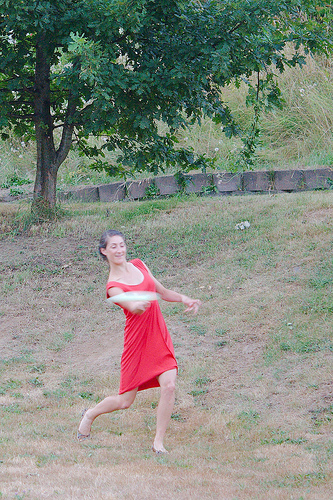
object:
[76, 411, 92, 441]
shoe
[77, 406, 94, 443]
foot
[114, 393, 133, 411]
knees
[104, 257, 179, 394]
dress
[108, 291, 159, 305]
frisbee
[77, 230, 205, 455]
woman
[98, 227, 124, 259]
hair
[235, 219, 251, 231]
leaf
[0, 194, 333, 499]
ground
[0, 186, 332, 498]
grass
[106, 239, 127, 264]
face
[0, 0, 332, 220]
tree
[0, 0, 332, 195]
grass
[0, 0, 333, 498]
park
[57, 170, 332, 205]
wall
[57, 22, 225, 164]
branch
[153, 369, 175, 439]
leg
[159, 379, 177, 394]
knee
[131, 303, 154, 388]
line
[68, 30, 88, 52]
leaf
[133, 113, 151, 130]
leaf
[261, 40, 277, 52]
leaf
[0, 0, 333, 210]
background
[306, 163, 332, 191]
stones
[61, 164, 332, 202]
formation